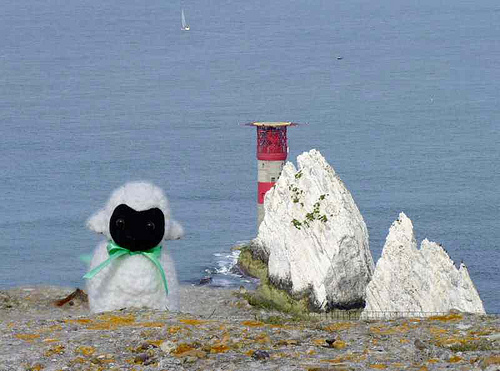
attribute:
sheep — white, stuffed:
[81, 181, 183, 315]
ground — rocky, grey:
[5, 307, 499, 370]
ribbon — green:
[85, 241, 169, 296]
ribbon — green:
[105, 242, 162, 258]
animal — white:
[85, 181, 186, 302]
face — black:
[112, 207, 163, 251]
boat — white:
[179, 7, 190, 33]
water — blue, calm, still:
[2, 1, 499, 119]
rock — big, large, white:
[259, 152, 370, 311]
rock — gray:
[362, 212, 485, 317]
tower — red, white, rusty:
[248, 118, 297, 191]